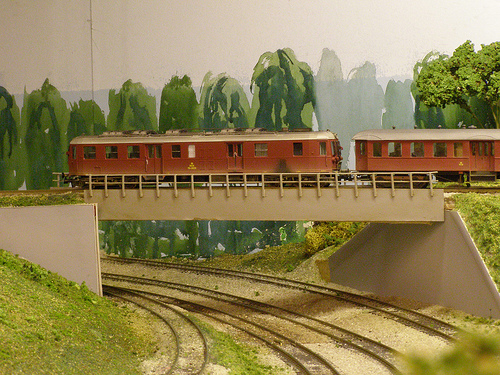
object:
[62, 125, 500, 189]
train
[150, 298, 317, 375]
train tracks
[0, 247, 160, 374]
grass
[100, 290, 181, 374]
railroad track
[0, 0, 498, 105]
blue sky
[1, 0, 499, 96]
white clouds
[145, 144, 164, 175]
door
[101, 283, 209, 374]
tracks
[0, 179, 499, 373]
ground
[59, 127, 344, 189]
train car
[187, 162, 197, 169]
sign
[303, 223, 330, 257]
bush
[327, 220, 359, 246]
bush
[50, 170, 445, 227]
bridge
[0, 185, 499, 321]
concrete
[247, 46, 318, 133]
painted trees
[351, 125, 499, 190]
car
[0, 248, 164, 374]
hillside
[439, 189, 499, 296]
hillside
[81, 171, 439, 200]
guard rail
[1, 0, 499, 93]
cloud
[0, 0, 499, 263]
backdrop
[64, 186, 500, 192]
tracks